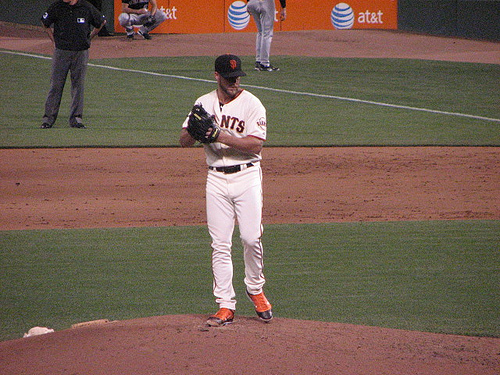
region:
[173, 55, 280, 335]
Baseball player in white uniform.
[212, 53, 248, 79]
Black hat with orange logo.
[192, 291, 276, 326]
Orange and black shoes.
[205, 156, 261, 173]
Black belt worn by player.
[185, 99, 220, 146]
Black leather mitt being worn by player.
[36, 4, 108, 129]
Umpire wearing black shirt.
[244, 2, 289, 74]
Player in light grey pants standing up.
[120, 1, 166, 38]
Player in light grey pants squatting down.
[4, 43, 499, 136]
White line painted across grass.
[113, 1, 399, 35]
AT&T ad on orange billboard.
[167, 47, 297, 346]
the pitcher on the mound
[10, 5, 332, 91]
players on the field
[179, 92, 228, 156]
the glove of the pitcher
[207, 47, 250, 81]
the pitcher wearing hat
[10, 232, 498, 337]
the grass on the field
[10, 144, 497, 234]
dirt on the field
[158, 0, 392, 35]
the advertisement on the wall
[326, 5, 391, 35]
the logo on the advertisement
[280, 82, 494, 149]
the line painted on the grass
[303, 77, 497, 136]
the line is white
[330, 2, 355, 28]
blue and white at&t logo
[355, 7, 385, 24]
white print on a wall reading at&t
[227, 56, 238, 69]
bright orange logo on a black cap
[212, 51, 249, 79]
black and orange baseball hat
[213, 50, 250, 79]
baseball cap on a baseball player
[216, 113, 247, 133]
lettering on a baseball jersey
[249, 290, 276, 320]
black and orange cleat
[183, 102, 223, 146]
black glove on a baseball player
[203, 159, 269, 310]
white pants on a baseball player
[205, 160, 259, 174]
black belt around a baseball player's waist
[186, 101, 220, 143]
The baseball glove.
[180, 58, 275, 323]
The baseball player gets ready to pitch.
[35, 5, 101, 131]
Security stands on the field.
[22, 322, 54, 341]
A towel for the pitcher lays on the floor.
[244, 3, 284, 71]
A player waits for the pitch.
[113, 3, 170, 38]
Another player waits for the pitch.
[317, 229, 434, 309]
Beautiful green grass.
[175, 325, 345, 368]
The pitcher's mound looks clean.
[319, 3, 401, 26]
AT&T billboard for advertising.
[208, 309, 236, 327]
The pitcher's bright shoes.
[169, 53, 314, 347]
pitcher standing on the mound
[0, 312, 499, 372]
small mound of dirt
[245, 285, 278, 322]
heel is lifted off the ground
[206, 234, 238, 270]
wrinkles on the pants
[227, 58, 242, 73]
small logo on the hat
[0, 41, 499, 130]
white line on the field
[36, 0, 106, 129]
umpire standing on the field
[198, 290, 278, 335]
orange and black shoes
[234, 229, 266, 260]
knee is bent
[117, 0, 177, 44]
player crouching in the dirt